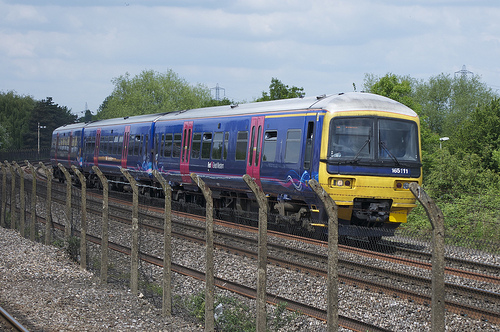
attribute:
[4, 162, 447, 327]
poles — bent, steel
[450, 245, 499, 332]
fencing — wire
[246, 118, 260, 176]
doors — red, double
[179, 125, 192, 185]
doors — red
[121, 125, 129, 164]
doors — red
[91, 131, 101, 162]
doors — red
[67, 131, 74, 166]
doors — red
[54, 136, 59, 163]
doors — red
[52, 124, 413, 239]
train — blue, commuter, passenger, yellow, short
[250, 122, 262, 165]
windows — oval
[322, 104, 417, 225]
front — yellow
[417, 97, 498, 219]
trees — growing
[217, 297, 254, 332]
plants — growing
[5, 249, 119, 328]
gravel — grey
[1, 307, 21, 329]
rails — filled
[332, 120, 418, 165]
windows — double, big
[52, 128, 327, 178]
cars — blue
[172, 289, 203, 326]
weeds — growing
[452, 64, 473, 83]
tower — tall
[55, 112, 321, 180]
side — red, blue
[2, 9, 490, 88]
sky — cloudy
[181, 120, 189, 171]
door — double, red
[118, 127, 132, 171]
door — double, red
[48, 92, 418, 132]
roof — grey